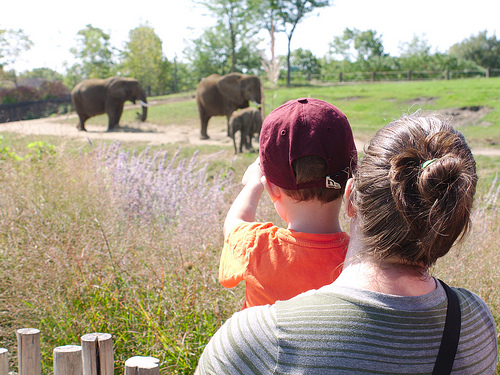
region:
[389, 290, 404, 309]
edge of a collar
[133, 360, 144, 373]
part of a pole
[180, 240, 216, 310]
part of a ground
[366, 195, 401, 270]
hair of a lady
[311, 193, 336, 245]
part of a neck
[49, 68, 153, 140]
an elephant feeding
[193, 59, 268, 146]
an elephant and its calf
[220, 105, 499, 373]
a boy and his mother watching the elephants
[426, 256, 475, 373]
a bag strap opn the mothers shoulder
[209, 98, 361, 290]
the boy is pointing the elephants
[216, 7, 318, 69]
tall green trees are on the distance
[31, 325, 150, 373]
small wooden poles acting as a fence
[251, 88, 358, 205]
the boy has put on a maroon cap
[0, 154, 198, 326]
the grass is tall and dried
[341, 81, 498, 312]
the ladies hair is tied on her back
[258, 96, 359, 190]
a maroon hat on a boy's head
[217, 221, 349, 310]
an orange shirt on a boy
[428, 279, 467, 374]
a black strap across a woman's back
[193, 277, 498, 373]
a gray striped shirt on a woman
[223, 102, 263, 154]
a baby elephant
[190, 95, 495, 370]
a woman holding a small boy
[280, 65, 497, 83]
a wooden fence in the background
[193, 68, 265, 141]
an adult elephant next to a baby elephant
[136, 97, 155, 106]
the white tusk of an elephant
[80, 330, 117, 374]
a split wooden post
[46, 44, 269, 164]
three gray elephants at the zoo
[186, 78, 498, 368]
two people looking at the elephants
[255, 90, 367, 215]
child wearing a baseball hat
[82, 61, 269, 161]
two adult elephants and one baby elephant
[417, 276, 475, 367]
black purse strap around woman's shoulder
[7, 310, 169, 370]
wooden fence posts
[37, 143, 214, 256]
tall dry grass and brush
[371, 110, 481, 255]
woman's brown hair tied in a bun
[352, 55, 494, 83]
wooden fence in the background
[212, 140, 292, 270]
child pointing at elephants with his left hand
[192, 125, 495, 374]
a woman holding a child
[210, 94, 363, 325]
a small boy looking over a fence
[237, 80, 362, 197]
a dark red hat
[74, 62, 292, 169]
a group of elephants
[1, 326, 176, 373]
the top of a wooden fence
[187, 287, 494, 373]
a gray striped shirt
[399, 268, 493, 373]
a black strap over a woman's shoulder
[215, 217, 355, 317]
a bright orange t-shirt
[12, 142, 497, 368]
a patch of tall weeds inside an enclosure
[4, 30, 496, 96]
a row of trees in the background